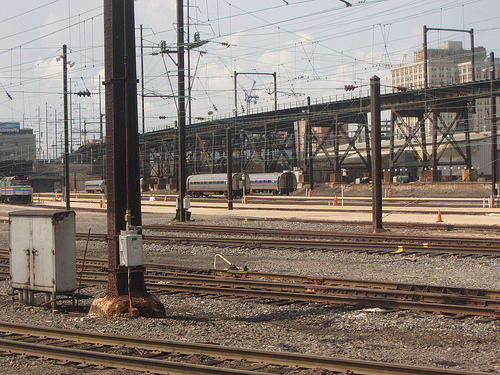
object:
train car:
[243, 172, 297, 195]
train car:
[187, 174, 251, 198]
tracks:
[0, 317, 498, 372]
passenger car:
[186, 173, 250, 197]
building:
[391, 41, 500, 176]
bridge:
[139, 77, 499, 147]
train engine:
[0, 177, 33, 205]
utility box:
[9, 209, 75, 293]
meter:
[119, 223, 144, 267]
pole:
[123, 2, 132, 215]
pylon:
[436, 208, 444, 222]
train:
[85, 180, 105, 192]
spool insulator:
[56, 55, 65, 62]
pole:
[63, 43, 69, 207]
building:
[1, 120, 36, 164]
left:
[3, 3, 110, 374]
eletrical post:
[174, 0, 187, 220]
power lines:
[2, 5, 498, 119]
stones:
[181, 291, 457, 368]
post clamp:
[125, 210, 135, 223]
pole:
[90, 0, 164, 318]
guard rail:
[213, 195, 500, 209]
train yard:
[2, 153, 497, 372]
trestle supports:
[382, 111, 478, 184]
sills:
[393, 161, 471, 167]